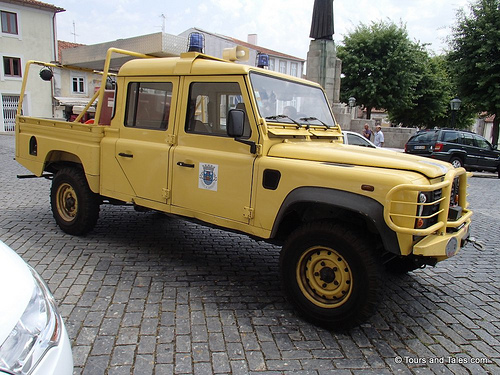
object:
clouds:
[181, 1, 248, 25]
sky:
[38, 0, 480, 78]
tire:
[278, 220, 388, 332]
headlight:
[0, 277, 65, 374]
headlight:
[417, 192, 429, 219]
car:
[13, 31, 486, 334]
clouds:
[406, 3, 452, 34]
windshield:
[246, 70, 336, 127]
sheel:
[278, 220, 386, 332]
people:
[362, 123, 384, 148]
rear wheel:
[49, 166, 103, 236]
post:
[452, 111, 457, 129]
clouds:
[86, 2, 130, 26]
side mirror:
[226, 109, 256, 154]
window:
[183, 82, 251, 141]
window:
[124, 81, 172, 132]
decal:
[198, 162, 219, 192]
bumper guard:
[382, 166, 473, 257]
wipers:
[265, 115, 331, 129]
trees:
[335, 16, 455, 131]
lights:
[348, 96, 357, 107]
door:
[170, 74, 262, 226]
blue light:
[187, 31, 206, 49]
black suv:
[404, 125, 499, 173]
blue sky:
[32, 0, 481, 78]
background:
[0, 0, 499, 58]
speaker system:
[222, 44, 250, 61]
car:
[0, 240, 91, 375]